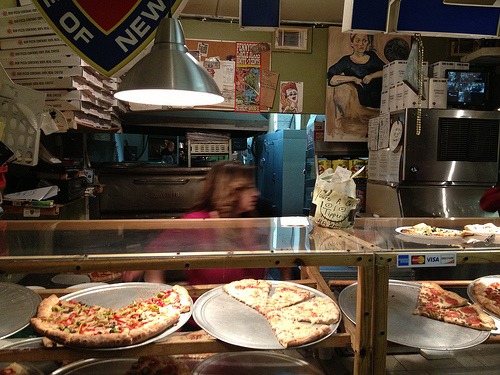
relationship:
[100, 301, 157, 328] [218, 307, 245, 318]
pizza on pan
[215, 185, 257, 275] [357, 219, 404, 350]
woman behind counter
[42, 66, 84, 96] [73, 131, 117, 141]
boxes on shelf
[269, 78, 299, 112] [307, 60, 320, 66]
painting on wall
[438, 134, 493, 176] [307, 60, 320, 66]
stove by wall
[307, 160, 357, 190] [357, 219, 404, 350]
trash on counter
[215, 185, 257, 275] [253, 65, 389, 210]
woman in kitchen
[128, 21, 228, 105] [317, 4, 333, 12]
light on ceiling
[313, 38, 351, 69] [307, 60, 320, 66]
picture on wall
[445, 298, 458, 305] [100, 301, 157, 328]
pepperoni on pizza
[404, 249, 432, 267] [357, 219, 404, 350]
sticker on counter